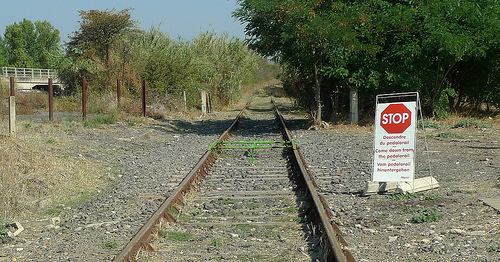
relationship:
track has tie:
[114, 93, 355, 261] [199, 173, 291, 177]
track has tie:
[114, 93, 355, 261] [183, 213, 301, 219]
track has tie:
[114, 93, 355, 261] [169, 221, 303, 227]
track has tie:
[114, 93, 355, 261] [214, 164, 289, 167]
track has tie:
[114, 93, 355, 261] [195, 196, 300, 200]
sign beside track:
[373, 102, 418, 191] [114, 93, 355, 261]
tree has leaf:
[233, 0, 368, 132] [310, 22, 318, 31]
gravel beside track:
[5, 109, 494, 259] [114, 93, 355, 261]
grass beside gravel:
[3, 102, 153, 235] [5, 109, 494, 259]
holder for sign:
[373, 93, 434, 196] [373, 102, 418, 191]